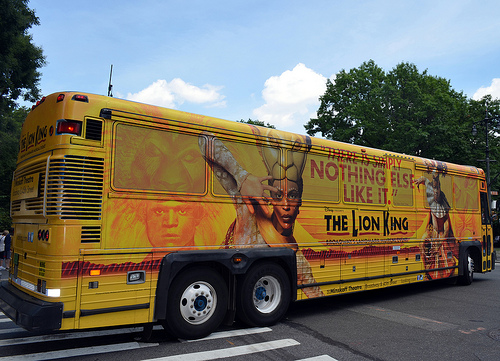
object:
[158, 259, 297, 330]
wheels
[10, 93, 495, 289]
bus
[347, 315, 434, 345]
road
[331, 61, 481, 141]
trees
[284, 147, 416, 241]
ad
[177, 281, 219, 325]
rim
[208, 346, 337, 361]
lines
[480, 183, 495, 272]
doors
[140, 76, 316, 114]
clouds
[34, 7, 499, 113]
sky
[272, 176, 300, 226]
face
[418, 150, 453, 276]
animal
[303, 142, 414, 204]
red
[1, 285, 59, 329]
bumper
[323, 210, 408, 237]
black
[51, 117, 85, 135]
lights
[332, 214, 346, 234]
letter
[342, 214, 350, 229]
e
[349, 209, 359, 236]
l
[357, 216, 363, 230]
i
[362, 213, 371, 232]
o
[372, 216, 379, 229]
n